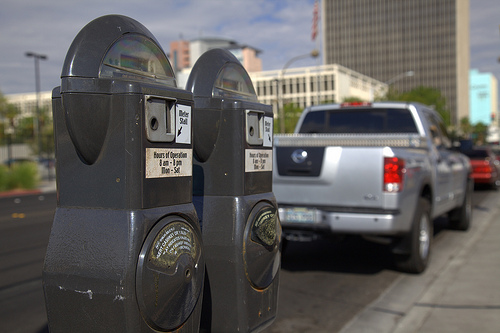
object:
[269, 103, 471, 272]
truck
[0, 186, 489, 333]
street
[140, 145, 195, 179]
sticker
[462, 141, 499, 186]
car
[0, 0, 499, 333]
background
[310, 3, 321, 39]
american flag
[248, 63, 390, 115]
building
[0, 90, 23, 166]
trees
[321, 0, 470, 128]
building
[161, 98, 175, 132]
slot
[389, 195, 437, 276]
tire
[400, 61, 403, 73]
windows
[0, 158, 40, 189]
green plant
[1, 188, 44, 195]
clay planter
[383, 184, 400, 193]
tail light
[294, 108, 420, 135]
window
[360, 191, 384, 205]
logo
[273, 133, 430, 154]
toolbox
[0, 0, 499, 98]
sky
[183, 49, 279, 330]
parking meter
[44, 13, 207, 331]
parking meter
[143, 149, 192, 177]
sign